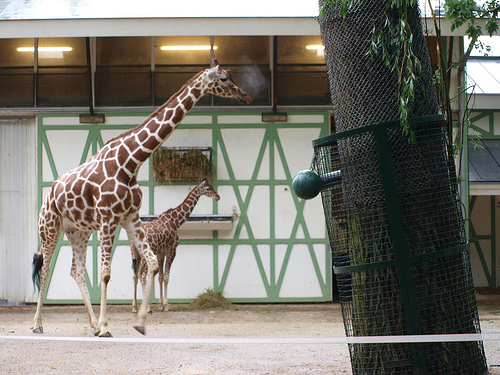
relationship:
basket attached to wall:
[153, 143, 213, 189] [35, 115, 346, 300]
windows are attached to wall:
[3, 38, 338, 110] [8, 40, 344, 299]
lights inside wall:
[16, 36, 327, 69] [35, 115, 346, 300]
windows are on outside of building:
[3, 38, 338, 110] [1, 2, 497, 325]